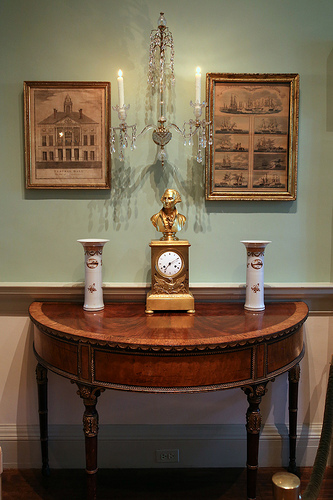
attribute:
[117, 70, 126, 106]
candle — white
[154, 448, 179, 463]
outlet — plastic, white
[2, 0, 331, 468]
wall — pale peach, green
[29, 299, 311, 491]
table — wood, polished, wooden, dark brown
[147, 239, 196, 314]
clock — gold, white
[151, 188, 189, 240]
statue — george washington, gold bust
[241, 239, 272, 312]
vase — white, gold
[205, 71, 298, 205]
picture — framed, painting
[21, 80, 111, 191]
picture — framed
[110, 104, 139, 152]
candle holder — crystal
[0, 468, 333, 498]
floor — wood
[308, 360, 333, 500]
rope — velvet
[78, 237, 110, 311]
vase — white